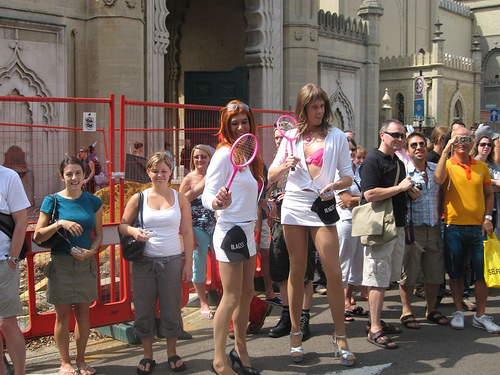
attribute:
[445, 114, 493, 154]
hat — Black 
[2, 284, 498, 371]
floor —  rough,  tarmac 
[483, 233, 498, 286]
bag — yellow 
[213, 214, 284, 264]
hat — Black 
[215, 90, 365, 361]
people — tall 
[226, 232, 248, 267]
cap — black 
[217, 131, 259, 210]
racket — pink 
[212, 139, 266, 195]
badmiton racket — pink 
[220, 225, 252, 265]
hat — Black 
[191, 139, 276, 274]
outfit — white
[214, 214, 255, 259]
hat — black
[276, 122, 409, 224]
shirt — blue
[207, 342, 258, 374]
heels — black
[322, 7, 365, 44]
building roof — white 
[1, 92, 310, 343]
fence — red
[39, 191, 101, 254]
blouse — blue 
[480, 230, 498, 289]
bag — yellow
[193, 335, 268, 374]
shoes — black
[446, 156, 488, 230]
shirt — orange 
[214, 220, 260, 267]
hat — Black 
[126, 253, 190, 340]
short — grey 